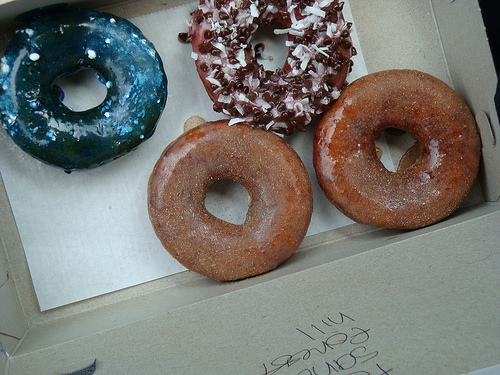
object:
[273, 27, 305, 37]
coconut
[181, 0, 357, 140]
doughnut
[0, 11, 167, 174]
doughnut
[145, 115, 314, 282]
doughnut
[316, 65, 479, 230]
doughnut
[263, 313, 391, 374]
writing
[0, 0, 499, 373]
box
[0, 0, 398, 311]
paper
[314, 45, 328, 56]
speck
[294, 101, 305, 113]
speck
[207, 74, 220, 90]
speck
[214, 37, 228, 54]
speck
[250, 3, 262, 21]
speck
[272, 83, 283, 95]
piece of chocolate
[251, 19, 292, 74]
hole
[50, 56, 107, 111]
hole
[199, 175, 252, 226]
hole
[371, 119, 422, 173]
hole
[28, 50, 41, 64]
sprinkle